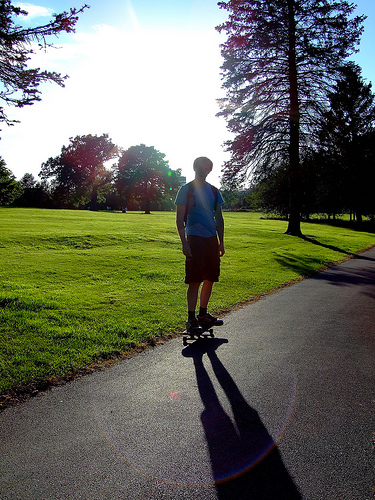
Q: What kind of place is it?
A: It is a park.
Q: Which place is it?
A: It is a park.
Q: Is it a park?
A: Yes, it is a park.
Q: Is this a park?
A: Yes, it is a park.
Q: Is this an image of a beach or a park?
A: It is showing a park.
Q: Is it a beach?
A: No, it is a park.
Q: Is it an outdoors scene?
A: Yes, it is outdoors.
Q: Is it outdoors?
A: Yes, it is outdoors.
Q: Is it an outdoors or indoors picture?
A: It is outdoors.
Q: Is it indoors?
A: No, it is outdoors.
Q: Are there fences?
A: No, there are no fences.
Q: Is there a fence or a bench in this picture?
A: No, there are no fences or benches.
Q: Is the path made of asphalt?
A: Yes, the path is made of asphalt.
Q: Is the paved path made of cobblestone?
A: No, the path is made of asphalt.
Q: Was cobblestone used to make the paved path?
A: No, the path is made of asphalt.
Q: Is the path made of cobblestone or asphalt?
A: The path is made of asphalt.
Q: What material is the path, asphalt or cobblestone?
A: The path is made of asphalt.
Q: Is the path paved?
A: Yes, the path is paved.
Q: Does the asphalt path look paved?
A: Yes, the path is paved.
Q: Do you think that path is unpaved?
A: No, the path is paved.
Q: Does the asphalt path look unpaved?
A: No, the path is paved.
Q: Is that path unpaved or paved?
A: The path is paved.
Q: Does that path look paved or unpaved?
A: The path is paved.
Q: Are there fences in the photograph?
A: No, there are no fences.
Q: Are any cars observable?
A: No, there are no cars.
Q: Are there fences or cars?
A: No, there are no cars or fences.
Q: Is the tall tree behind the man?
A: Yes, the tree is behind the man.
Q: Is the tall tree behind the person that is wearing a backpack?
A: Yes, the tree is behind the man.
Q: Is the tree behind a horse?
A: No, the tree is behind the man.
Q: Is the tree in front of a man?
A: No, the tree is behind a man.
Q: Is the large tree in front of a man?
A: No, the tree is behind a man.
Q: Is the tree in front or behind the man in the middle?
A: The tree is behind the man.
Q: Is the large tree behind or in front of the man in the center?
A: The tree is behind the man.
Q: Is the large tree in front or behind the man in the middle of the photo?
A: The tree is behind the man.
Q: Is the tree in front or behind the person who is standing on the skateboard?
A: The tree is behind the man.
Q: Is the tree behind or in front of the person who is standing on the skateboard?
A: The tree is behind the man.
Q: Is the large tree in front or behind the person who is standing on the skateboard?
A: The tree is behind the man.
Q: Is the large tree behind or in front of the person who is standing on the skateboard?
A: The tree is behind the man.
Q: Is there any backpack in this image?
A: Yes, there is a backpack.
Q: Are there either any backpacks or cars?
A: Yes, there is a backpack.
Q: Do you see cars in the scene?
A: No, there are no cars.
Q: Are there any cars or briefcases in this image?
A: No, there are no cars or briefcases.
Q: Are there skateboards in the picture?
A: Yes, there is a skateboard.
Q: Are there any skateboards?
A: Yes, there is a skateboard.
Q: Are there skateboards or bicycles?
A: Yes, there is a skateboard.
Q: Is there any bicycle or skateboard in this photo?
A: Yes, there is a skateboard.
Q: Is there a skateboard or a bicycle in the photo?
A: Yes, there is a skateboard.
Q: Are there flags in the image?
A: No, there are no flags.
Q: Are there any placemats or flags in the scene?
A: No, there are no flags or placemats.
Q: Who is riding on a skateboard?
A: The man is riding on a skateboard.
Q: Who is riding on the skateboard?
A: The man is riding on a skateboard.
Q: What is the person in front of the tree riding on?
A: The man is riding on a skateboard.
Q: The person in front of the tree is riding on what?
A: The man is riding on a skateboard.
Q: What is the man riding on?
A: The man is riding on a skateboard.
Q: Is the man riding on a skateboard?
A: Yes, the man is riding on a skateboard.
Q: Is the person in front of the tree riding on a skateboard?
A: Yes, the man is riding on a skateboard.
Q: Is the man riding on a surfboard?
A: No, the man is riding on a skateboard.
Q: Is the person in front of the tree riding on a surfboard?
A: No, the man is riding on a skateboard.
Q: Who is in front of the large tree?
A: The man is in front of the tree.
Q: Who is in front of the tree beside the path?
A: The man is in front of the tree.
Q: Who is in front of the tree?
A: The man is in front of the tree.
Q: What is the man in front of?
A: The man is in front of the tree.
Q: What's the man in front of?
A: The man is in front of the tree.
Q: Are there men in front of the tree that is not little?
A: Yes, there is a man in front of the tree.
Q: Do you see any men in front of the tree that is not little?
A: Yes, there is a man in front of the tree.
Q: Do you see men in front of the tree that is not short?
A: Yes, there is a man in front of the tree.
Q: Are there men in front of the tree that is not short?
A: Yes, there is a man in front of the tree.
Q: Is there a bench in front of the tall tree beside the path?
A: No, there is a man in front of the tree.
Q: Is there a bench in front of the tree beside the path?
A: No, there is a man in front of the tree.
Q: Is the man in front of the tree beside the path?
A: Yes, the man is in front of the tree.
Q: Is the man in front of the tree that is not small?
A: Yes, the man is in front of the tree.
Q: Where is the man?
A: The man is on the path.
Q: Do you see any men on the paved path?
A: Yes, there is a man on the path.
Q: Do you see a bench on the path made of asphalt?
A: No, there is a man on the path.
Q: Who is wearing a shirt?
A: The man is wearing a shirt.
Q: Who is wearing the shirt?
A: The man is wearing a shirt.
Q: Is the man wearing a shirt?
A: Yes, the man is wearing a shirt.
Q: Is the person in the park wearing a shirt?
A: Yes, the man is wearing a shirt.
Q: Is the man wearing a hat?
A: No, the man is wearing a shirt.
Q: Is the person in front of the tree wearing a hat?
A: No, the man is wearing a shirt.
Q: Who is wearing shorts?
A: The man is wearing shorts.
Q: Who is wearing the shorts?
A: The man is wearing shorts.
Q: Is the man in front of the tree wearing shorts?
A: Yes, the man is wearing shorts.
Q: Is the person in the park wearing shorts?
A: Yes, the man is wearing shorts.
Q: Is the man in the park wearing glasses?
A: No, the man is wearing shorts.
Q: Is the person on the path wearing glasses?
A: No, the man is wearing shorts.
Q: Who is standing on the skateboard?
A: The man is standing on the skateboard.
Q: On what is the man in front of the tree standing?
A: The man is standing on the skateboard.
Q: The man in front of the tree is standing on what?
A: The man is standing on the skateboard.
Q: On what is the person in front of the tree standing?
A: The man is standing on the skateboard.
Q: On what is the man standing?
A: The man is standing on the skateboard.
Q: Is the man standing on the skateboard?
A: Yes, the man is standing on the skateboard.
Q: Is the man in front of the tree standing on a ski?
A: No, the man is standing on the skateboard.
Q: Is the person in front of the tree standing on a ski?
A: No, the man is standing on the skateboard.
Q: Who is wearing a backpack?
A: The man is wearing a backpack.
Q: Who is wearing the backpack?
A: The man is wearing a backpack.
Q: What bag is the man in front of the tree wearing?
A: The man is wearing a backpack.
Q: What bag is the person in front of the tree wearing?
A: The man is wearing a backpack.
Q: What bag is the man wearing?
A: The man is wearing a backpack.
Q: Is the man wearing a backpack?
A: Yes, the man is wearing a backpack.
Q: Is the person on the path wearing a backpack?
A: Yes, the man is wearing a backpack.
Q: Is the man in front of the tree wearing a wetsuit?
A: No, the man is wearing a backpack.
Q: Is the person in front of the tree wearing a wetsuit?
A: No, the man is wearing a backpack.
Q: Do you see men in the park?
A: Yes, there is a man in the park.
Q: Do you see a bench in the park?
A: No, there is a man in the park.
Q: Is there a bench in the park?
A: No, there is a man in the park.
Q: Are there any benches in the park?
A: No, there is a man in the park.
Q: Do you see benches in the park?
A: No, there is a man in the park.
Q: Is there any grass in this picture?
A: Yes, there is grass.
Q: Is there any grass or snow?
A: Yes, there is grass.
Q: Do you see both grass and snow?
A: No, there is grass but no snow.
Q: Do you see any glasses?
A: No, there are no glasses.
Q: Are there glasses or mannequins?
A: No, there are no glasses or mannequins.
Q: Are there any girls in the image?
A: No, there are no girls.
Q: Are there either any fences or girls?
A: No, there are no girls or fences.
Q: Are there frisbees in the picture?
A: No, there are no frisbees.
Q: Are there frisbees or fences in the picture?
A: No, there are no frisbees or fences.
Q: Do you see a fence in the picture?
A: No, there are no fences.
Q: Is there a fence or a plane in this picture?
A: No, there are no fences or airplanes.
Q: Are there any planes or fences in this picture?
A: No, there are no fences or planes.